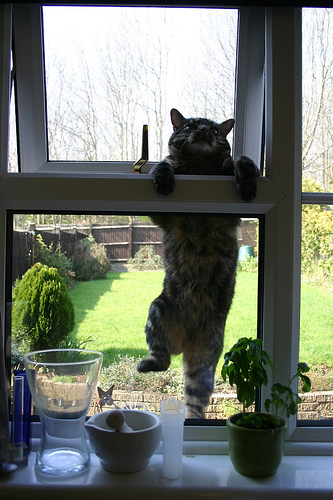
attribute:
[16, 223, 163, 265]
fence — brown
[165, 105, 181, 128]
ear —  cat's, the  right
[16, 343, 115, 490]
vase — glass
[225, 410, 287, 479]
pot — green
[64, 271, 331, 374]
grass — green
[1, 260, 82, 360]
bush — green, trimmed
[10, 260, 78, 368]
shrub — green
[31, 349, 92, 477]
hourglass —  vase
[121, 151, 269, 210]
legs — grey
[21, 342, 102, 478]
vase — small, clear, glass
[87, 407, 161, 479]
mortar — ceramic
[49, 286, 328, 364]
grass — green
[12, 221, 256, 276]
fence — wooden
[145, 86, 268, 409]
cat — grey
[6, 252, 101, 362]
bush —  outside,  large,  green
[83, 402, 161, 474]
pestal — white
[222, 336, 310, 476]
potted plant — small 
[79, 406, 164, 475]
pestle — white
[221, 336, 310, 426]
plant —  green,  small, green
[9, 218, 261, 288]
fence — wood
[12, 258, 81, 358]
bush — green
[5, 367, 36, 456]
vase — blue, long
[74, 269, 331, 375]
lawn — green, trimmed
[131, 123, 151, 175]
window latch — shiny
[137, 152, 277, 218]
paws — dark grey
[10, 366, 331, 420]
brick wall —  brick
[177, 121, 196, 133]
eye —  cat's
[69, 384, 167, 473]
morter — white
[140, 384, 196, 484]
container — plastic